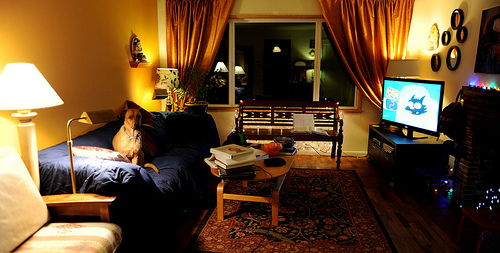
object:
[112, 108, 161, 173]
dog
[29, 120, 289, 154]
floor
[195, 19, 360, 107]
window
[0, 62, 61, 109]
shade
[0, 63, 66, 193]
lamp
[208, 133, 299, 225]
coffee table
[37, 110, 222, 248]
blue couch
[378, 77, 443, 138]
television